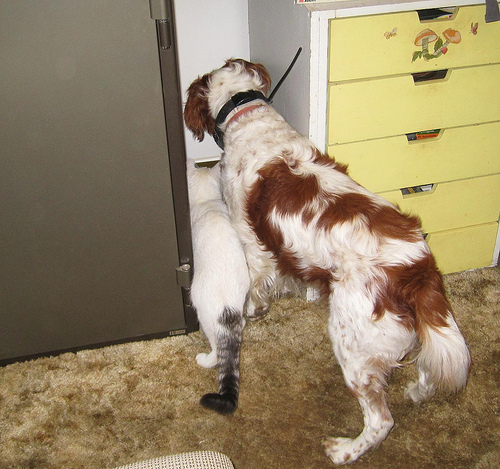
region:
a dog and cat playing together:
[170, 61, 468, 449]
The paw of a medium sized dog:
[322, 419, 349, 463]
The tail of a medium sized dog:
[388, 269, 468, 400]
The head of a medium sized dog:
[170, 59, 264, 129]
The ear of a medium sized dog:
[184, 81, 219, 142]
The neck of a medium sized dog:
[215, 82, 275, 144]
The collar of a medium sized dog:
[202, 82, 276, 119]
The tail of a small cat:
[198, 299, 252, 404]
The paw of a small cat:
[181, 339, 222, 371]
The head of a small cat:
[191, 163, 228, 200]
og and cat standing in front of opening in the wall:
[169, 53, 478, 467]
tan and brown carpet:
[2, 270, 495, 466]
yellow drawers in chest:
[313, 0, 497, 298]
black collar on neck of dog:
[209, 87, 274, 158]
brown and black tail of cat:
[197, 305, 247, 421]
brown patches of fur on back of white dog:
[243, 135, 453, 342]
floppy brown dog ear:
[176, 78, 215, 144]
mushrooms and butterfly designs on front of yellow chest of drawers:
[372, 17, 494, 65]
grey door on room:
[2, 0, 211, 379]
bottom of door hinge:
[146, 1, 183, 56]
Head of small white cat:
[185, 157, 225, 199]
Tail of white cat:
[196, 310, 250, 417]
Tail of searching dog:
[399, 303, 473, 408]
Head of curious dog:
[181, 56, 278, 143]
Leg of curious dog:
[316, 363, 399, 467]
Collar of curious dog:
[208, 86, 273, 131]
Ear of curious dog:
[181, 83, 211, 139]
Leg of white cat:
[191, 315, 222, 375]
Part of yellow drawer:
[338, 93, 404, 115]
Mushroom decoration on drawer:
[401, 23, 465, 67]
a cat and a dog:
[156, 43, 401, 396]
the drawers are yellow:
[327, 15, 497, 383]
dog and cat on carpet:
[154, 45, 476, 467]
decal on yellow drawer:
[404, 28, 471, 65]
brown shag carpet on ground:
[29, 369, 191, 444]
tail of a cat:
[205, 319, 248, 421]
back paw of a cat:
[318, 428, 370, 466]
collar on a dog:
[205, 89, 275, 119]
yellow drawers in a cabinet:
[306, 10, 496, 272]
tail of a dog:
[388, 230, 477, 423]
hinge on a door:
[168, 260, 197, 304]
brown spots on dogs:
[323, 188, 398, 239]